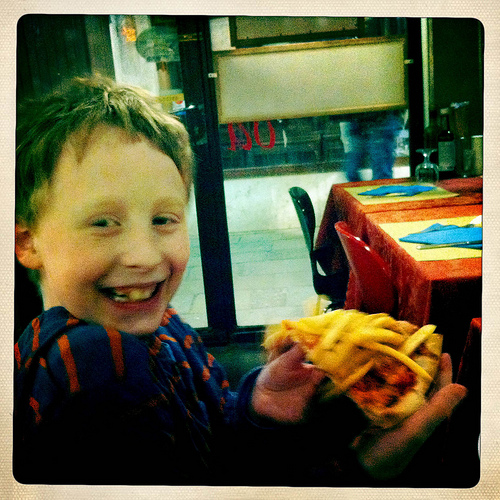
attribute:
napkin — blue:
[404, 211, 484, 253]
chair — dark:
[331, 218, 401, 317]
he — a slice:
[10, 72, 467, 483]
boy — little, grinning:
[15, 74, 324, 482]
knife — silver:
[413, 233, 482, 258]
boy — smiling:
[17, 90, 300, 485]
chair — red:
[330, 218, 396, 312]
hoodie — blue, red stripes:
[23, 305, 226, 406]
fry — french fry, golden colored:
[277, 314, 387, 351]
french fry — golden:
[350, 316, 446, 357]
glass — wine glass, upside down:
[409, 142, 444, 187]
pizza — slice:
[261, 312, 437, 417]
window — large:
[172, 18, 440, 326]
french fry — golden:
[313, 351, 373, 385]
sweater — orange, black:
[15, 305, 263, 482]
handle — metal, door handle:
[184, 103, 207, 146]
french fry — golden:
[360, 334, 437, 384]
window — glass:
[201, 37, 421, 297]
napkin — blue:
[357, 182, 440, 198]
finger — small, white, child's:
[364, 384, 471, 458]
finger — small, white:
[259, 341, 322, 381]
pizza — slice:
[270, 284, 478, 421]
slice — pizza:
[308, 311, 439, 421]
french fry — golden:
[294, 307, 374, 359]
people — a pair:
[286, 70, 446, 181]